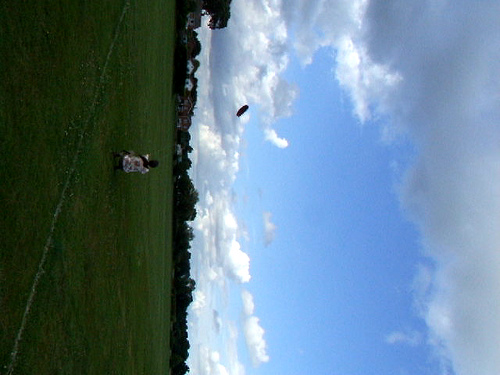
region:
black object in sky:
[231, 92, 253, 122]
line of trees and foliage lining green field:
[173, 3, 236, 373]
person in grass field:
[106, 137, 169, 186]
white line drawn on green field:
[3, 169, 78, 374]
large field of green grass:
[1, 4, 173, 372]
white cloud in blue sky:
[251, 116, 306, 174]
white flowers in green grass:
[68, 78, 100, 149]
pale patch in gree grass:
[109, 275, 135, 337]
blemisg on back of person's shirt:
[126, 155, 143, 172]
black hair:
[144, 153, 164, 173]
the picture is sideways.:
[5, 1, 495, 368]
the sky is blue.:
[182, 3, 497, 374]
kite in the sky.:
[232, 98, 252, 120]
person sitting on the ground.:
[116, 149, 165, 176]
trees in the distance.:
[163, 1, 235, 373]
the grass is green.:
[5, 2, 179, 373]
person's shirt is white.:
[122, 152, 154, 177]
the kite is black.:
[233, 100, 252, 122]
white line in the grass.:
[4, 0, 136, 372]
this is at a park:
[81, 62, 306, 332]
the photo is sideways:
[6, 20, 380, 320]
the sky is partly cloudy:
[306, 19, 498, 331]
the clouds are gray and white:
[401, 67, 466, 344]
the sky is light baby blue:
[255, 160, 381, 373]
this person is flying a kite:
[30, 115, 165, 246]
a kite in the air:
[232, 103, 250, 117]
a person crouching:
[111, 141, 160, 184]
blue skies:
[311, 167, 376, 310]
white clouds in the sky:
[223, 244, 270, 340]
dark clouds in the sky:
[393, 43, 475, 222]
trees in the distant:
[173, 120, 203, 300]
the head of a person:
[146, 153, 162, 174]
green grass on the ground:
[71, 253, 161, 361]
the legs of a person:
[113, 148, 123, 175]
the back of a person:
[128, 158, 141, 170]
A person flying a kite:
[104, 85, 279, 231]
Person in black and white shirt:
[91, 146, 166, 188]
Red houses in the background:
[164, 65, 219, 157]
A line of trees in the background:
[146, 138, 231, 363]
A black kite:
[204, 87, 261, 130]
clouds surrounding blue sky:
[187, 0, 499, 373]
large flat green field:
[3, 3, 177, 374]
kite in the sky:
[233, 102, 253, 119]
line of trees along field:
[171, 1, 231, 373]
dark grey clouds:
[358, 0, 499, 370]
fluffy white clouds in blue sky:
[190, 203, 270, 374]